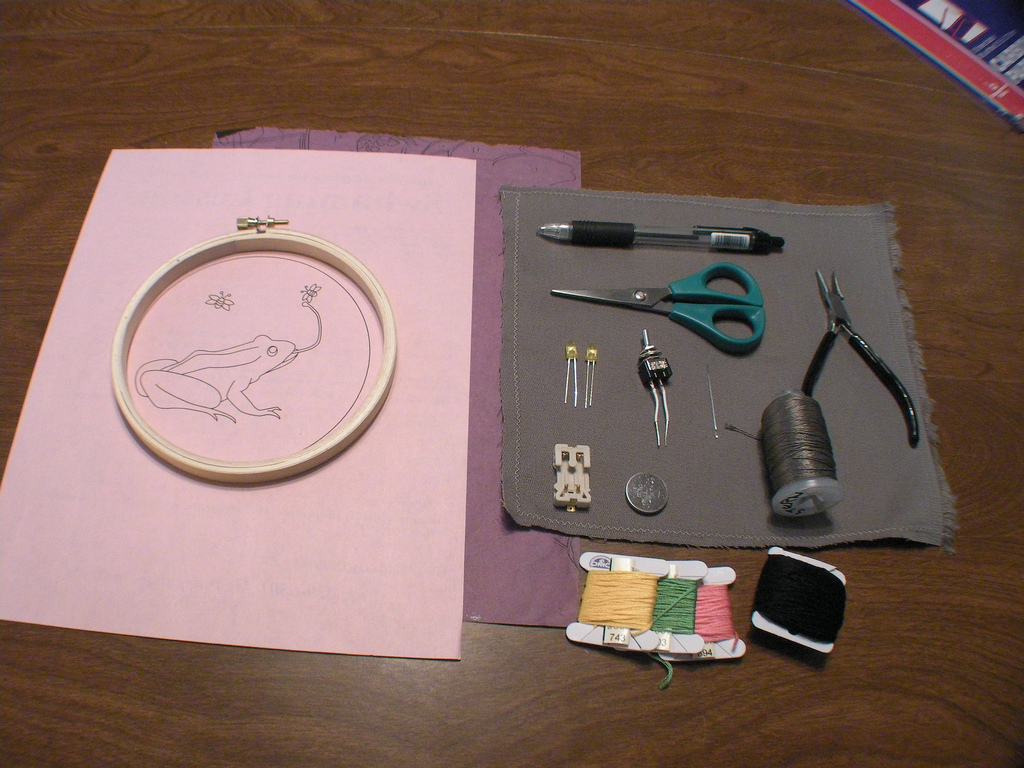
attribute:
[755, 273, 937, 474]
pliers — black, silver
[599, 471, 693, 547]
coin — silver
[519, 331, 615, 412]
resistors — small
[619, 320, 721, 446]
switch — small, electrical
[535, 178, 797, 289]
pen — black ink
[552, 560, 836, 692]
string — rolled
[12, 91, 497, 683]
paper — pink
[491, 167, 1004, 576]
cloth — gray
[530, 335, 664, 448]
resistors — small, pair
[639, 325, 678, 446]
switch — small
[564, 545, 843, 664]
string — various colors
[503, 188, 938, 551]
cloth — grey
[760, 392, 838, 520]
wire — grey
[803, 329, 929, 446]
handle — black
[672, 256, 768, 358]
handle — blue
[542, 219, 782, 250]
pen — clear, plastic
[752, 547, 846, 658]
thread — black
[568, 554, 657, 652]
thread — yellow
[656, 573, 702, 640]
thread — green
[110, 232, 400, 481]
ring — wooden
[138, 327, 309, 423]
frog — embroidered